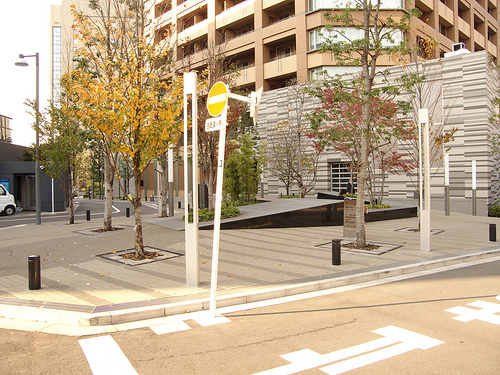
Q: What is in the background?
A: The tree with purple leaves.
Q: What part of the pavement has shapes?
A: White painted sections.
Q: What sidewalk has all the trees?
A: The corner near the building.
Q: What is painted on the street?
A: The street directions.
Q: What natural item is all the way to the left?
A: Planted sidewalk tree.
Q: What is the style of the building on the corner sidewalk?
A: Large and tan.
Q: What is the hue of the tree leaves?
A: Yellow.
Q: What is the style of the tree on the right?
A: Red and green.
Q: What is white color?
A: Sign post.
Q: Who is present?
A: Nobody.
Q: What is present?
A: A building.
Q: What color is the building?
A: Grey.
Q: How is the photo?
A: Clear.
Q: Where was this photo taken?
A: On the street.